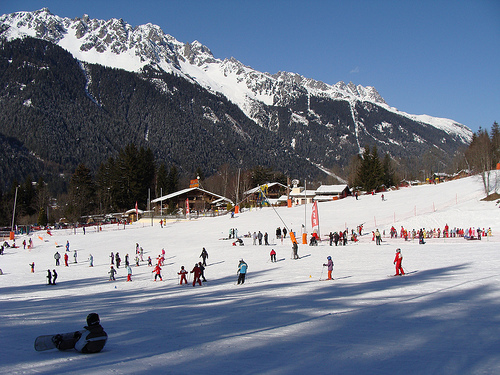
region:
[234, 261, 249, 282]
person standing on ski slope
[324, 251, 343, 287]
person standing on ski slope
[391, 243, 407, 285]
person standing on ski slope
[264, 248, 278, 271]
person standing on ski slope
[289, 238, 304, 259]
person standing on ski slope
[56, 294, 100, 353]
person standing on ski slope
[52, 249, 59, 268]
person standing on ski slope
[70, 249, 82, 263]
person standing on ski slope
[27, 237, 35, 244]
person standing on ski slope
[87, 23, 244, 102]
snow on side of mountains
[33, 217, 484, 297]
group of people skiing on hill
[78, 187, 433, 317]
group of people in the snow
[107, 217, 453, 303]
people skiing down hill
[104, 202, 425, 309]
people skiing on mountain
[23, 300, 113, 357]
man sitting down on hill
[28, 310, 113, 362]
man sitting down on mountain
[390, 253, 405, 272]
red ski suit on person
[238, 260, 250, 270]
blue snow jacket on person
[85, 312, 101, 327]
black helmet on person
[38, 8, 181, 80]
snow covering top of mountain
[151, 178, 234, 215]
The brown cabin with a red structure on its roof.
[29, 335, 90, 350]
The snowboard the person has on.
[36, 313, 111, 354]
The person sitting on the ground.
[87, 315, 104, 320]
The hat the person sitting on the ground is wearing.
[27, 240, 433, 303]
The people in the middle of the area skiing.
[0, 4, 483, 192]
The mountain in the background.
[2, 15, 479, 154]
The snow on the mountain in the background.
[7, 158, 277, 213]
The trees in front of the mountain.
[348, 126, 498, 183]
The trees on the right.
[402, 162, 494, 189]
The cabins on the right.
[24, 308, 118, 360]
Person falling down on a snowboard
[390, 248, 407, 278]
Person in red on a snowboard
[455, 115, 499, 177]
Dark trees on the top of the hill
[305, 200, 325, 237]
Red and white flag on the hill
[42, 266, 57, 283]
Two people going down the hill together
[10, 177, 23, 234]
Tall pole at the bottom of the hill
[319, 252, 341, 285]
Person in red pants holding a ski pole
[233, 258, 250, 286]
Person in a light blue jacket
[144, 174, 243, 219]
Brown building covered with snow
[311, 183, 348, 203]
Brown building with a roof covered with snow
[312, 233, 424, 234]
Group of people in the snow.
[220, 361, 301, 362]
Group of people in the snow.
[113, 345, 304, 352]
Group of people in the snow.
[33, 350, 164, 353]
Group of people in the snow.